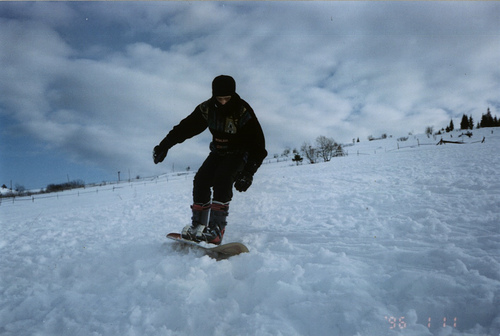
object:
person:
[153, 73, 266, 243]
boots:
[166, 200, 209, 246]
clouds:
[0, 0, 499, 73]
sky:
[0, 0, 500, 68]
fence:
[3, 135, 499, 202]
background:
[0, 113, 497, 227]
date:
[386, 316, 459, 329]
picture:
[0, 1, 500, 336]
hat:
[211, 75, 235, 95]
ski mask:
[214, 98, 235, 107]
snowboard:
[166, 228, 249, 259]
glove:
[153, 145, 168, 164]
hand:
[153, 145, 168, 164]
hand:
[233, 167, 252, 191]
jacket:
[162, 96, 267, 170]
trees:
[461, 114, 469, 129]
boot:
[207, 201, 228, 244]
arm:
[243, 113, 267, 173]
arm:
[158, 101, 209, 148]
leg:
[213, 152, 232, 248]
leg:
[193, 149, 212, 243]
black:
[211, 158, 231, 183]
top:
[384, 127, 498, 146]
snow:
[3, 142, 498, 327]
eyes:
[218, 97, 230, 100]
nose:
[222, 99, 226, 104]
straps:
[210, 211, 228, 216]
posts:
[32, 197, 34, 202]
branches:
[301, 134, 333, 153]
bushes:
[301, 134, 345, 164]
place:
[21, 163, 483, 328]